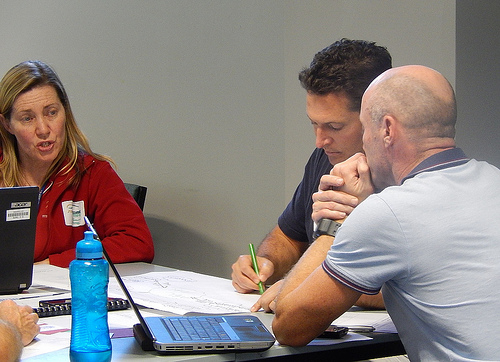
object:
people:
[0, 27, 498, 361]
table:
[0, 240, 409, 362]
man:
[232, 38, 409, 313]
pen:
[247, 235, 264, 296]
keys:
[163, 314, 233, 342]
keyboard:
[149, 306, 269, 349]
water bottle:
[67, 227, 115, 359]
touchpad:
[235, 321, 253, 335]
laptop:
[81, 211, 275, 355]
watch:
[309, 217, 342, 237]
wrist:
[310, 218, 344, 235]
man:
[223, 32, 496, 361]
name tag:
[61, 199, 85, 230]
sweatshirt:
[5, 155, 154, 274]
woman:
[0, 53, 154, 264]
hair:
[0, 56, 118, 192]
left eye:
[45, 110, 66, 122]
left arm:
[35, 158, 155, 279]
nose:
[35, 117, 52, 138]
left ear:
[383, 117, 402, 150]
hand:
[229, 250, 276, 296]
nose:
[312, 126, 334, 151]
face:
[304, 89, 367, 166]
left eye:
[328, 120, 345, 137]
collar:
[395, 146, 471, 181]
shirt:
[319, 146, 499, 360]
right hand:
[309, 170, 356, 224]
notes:
[109, 269, 285, 316]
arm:
[3, 289, 43, 362]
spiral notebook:
[18, 286, 131, 317]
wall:
[2, 3, 499, 280]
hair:
[298, 37, 393, 107]